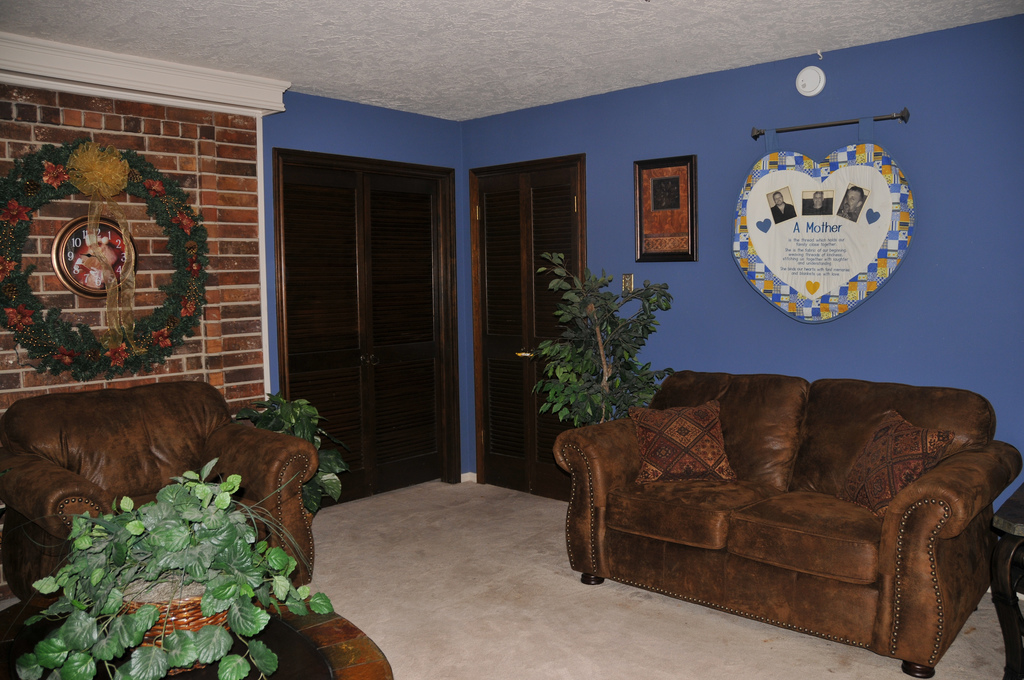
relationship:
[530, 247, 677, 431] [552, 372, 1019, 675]
plant next to couch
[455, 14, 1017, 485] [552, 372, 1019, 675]
wall behind couch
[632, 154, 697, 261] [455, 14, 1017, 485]
picture on wall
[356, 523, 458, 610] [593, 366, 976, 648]
rug in front couch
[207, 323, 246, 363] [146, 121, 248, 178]
bricks on the wall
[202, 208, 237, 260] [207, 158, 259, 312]
brick on the wall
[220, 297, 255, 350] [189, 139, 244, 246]
brick in a wall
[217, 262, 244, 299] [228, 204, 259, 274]
brick in a wall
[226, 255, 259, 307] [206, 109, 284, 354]
brick in a wall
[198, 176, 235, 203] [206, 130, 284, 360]
brick in a wall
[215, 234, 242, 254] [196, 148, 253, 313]
brick in a wall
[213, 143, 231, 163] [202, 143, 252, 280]
brick in a wall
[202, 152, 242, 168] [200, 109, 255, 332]
brick in a wall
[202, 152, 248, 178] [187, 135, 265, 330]
brick in a wall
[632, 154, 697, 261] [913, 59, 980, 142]
picture on a wall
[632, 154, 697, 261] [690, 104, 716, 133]
picture on a wall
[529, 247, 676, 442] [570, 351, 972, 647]
plant near a seat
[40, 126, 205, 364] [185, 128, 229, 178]
wreath on a wall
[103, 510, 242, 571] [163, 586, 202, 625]
plant in a basket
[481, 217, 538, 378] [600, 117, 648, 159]
door in a wall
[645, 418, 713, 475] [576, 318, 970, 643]
pillow on a seat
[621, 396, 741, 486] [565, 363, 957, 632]
pillow on the seat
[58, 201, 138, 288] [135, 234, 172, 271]
clock on the wall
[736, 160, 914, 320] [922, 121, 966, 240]
heart hanging on wall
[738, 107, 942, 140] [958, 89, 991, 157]
bar hanging on wall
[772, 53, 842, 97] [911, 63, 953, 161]
alarm on the wall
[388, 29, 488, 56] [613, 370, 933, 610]
ceiling above couch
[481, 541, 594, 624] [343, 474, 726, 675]
carpet on ground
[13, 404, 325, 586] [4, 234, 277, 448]
chair against wall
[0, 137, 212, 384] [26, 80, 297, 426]
wreath on brick wall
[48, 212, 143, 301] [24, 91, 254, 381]
clock on brick wall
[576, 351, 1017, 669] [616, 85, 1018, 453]
couch against wall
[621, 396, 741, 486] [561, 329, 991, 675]
pillow on couch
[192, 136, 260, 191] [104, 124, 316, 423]
brick on far wall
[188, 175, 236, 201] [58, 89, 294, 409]
brick on wall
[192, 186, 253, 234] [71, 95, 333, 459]
brick on wall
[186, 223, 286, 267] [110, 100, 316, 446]
brick on far wall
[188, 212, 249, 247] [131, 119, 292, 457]
brick on far wall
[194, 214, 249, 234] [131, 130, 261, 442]
brick on far wall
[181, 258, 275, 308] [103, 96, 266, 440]
brick on far wall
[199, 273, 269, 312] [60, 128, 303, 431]
brick on far wall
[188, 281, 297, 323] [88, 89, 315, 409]
brick on far wall